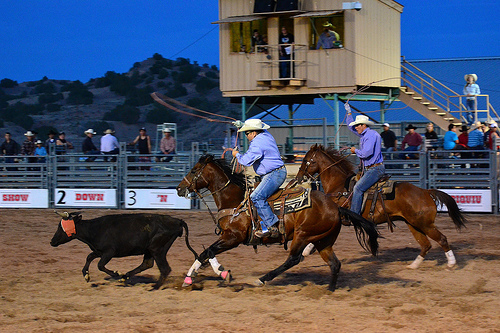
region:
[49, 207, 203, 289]
Black calf with horns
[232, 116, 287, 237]
Cowboy riding a horse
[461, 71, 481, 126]
Cowgirl standing on the stairs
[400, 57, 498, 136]
Stairs leading up to the announcer stand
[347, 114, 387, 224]
Cowboy wearing a white cowboy hat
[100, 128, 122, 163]
Cowboy with cowboy hat sitting backwards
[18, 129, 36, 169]
Cowboy watching the rodeo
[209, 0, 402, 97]
Announcer station with two windows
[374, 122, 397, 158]
Man with a white ball cap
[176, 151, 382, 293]
Brown horse chasing calf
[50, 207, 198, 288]
A young black bull.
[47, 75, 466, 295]
Two men on horses roping a bull.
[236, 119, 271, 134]
A white cowboy hat.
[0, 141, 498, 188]
A gray metal fence.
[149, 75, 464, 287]
Two cowboys with lassoes.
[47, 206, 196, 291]
A running black bull.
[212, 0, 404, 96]
A large beige metal building.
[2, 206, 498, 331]
A large brown sandy patch of ground.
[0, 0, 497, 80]
A deep blue sky.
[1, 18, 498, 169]
A crowd of spectators at a rodeo.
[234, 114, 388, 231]
two men wearing matching outfits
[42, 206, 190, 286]
a small calf being lassoed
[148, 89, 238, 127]
the circle of a lasso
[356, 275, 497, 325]
dirt with many footprints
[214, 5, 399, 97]
viewing box for the rodeo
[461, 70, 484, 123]
person with blue shirt and white hat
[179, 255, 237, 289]
wraps around a horse's ankles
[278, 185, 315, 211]
brown saddle with blanket underneath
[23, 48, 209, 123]
mountains with trees on them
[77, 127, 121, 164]
two people sitting on a fence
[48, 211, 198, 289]
Blindfolded black bull that is running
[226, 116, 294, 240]
Man in blue shirt, pants with white hat riding a horse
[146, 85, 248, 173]
brown lasso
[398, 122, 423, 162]
Man with blue jeans, red shirt, black hat sitting on bleachers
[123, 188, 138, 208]
Number three, black on white background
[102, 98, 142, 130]
green bush on brown dirt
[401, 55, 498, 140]
light brown stairs with railings and a woman standing on their platform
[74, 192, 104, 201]
The word "down," in captials, pink with white background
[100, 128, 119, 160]
man's backside, sitting on fence wearing black pants, light blue shirt and tan hat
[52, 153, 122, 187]
gray metal fencing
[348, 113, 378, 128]
a man's white hat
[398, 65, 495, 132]
a brown staircase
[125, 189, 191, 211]
a long white sign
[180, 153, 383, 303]
a large brown horse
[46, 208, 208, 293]
a small brown cow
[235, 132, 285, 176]
a man's long sleeve blue shirt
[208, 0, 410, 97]
a small brown trailer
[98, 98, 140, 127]
a small green shrub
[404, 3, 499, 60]
part of a blue sky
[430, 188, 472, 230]
a black horse tail